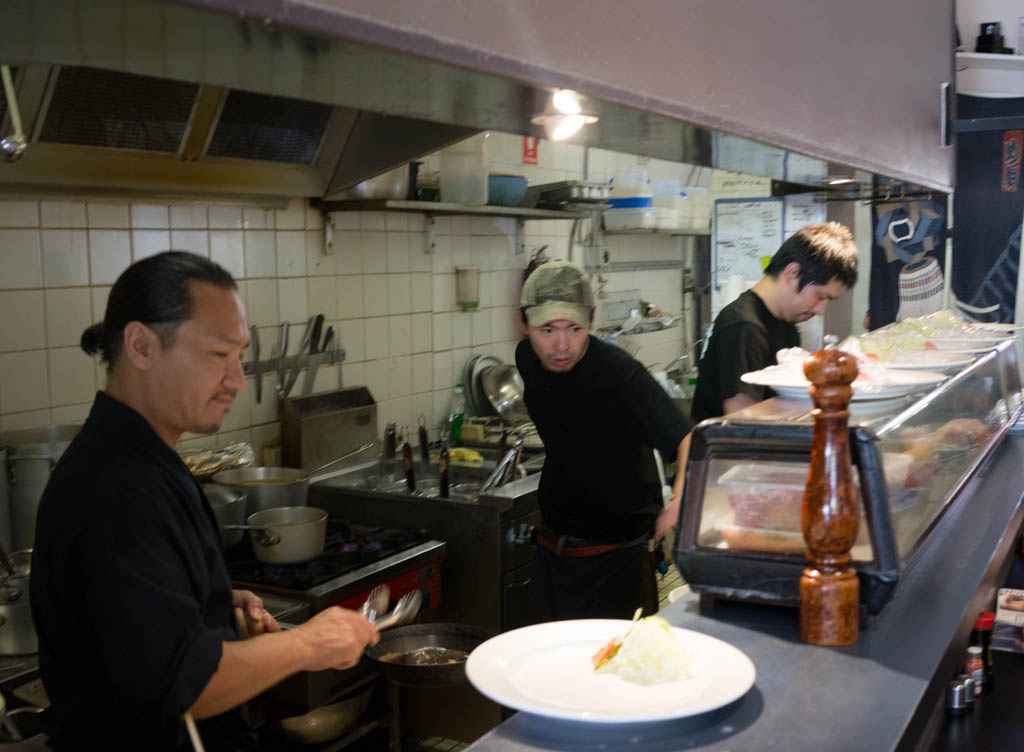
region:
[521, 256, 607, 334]
hat on man's head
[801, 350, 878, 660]
wooden pole on counter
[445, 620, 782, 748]
white plate on counter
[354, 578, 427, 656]
tongs in man's hand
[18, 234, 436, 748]
cook at the restaurant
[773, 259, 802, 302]
right ear on guy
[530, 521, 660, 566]
belt on man's waist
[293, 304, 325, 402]
knife hanging on rack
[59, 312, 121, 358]
ponytail in man's head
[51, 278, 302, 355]
Man has dark hair.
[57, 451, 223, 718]
Man wearing black shirt.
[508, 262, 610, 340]
Man wearing baseball cap.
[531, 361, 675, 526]
Man wearing black shirt.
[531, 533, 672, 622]
Man wearing black pants.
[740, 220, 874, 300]
Man has short hair.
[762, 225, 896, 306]
Man has black hair.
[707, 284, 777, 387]
Man wearing black shirt.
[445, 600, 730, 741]
White bowl on counter top.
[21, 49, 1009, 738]
picture of a kitchen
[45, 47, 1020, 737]
kitchen is in a restaurant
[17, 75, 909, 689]
three male chefs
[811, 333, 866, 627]
a tall pepper mill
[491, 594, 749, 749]
a white bowl on top of the counter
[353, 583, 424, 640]
the man holds metal tongs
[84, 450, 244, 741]
the man wears a black shirt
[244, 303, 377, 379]
knives are on the wall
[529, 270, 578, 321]
the man wears a green hat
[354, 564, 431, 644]
Man holding tongs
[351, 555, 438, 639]
Man is holding tongs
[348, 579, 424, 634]
Man holding a pair of tongs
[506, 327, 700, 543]
Man wearing a shirt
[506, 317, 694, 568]
Man is wearing a shirt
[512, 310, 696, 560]
Man wearing a black shirt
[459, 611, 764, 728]
White plate on a counter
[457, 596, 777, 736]
White plate is on a counter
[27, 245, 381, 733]
chef wearing a black colored shirt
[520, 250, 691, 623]
chef wearing a black colored shirt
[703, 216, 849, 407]
chef wearing a black colored shirt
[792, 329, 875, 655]
big wooden pole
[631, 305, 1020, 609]
display of food preparation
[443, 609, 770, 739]
plate on the lower counter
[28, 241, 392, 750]
man with a ponytail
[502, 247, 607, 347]
green colored baseball cap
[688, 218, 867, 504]
man looking down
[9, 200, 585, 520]
white tiled wall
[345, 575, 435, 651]
tongs in a man's hand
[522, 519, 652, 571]
brown belt on a man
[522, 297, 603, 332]
bill of a baseball cap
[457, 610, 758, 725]
large white plate on the counter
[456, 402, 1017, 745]
gray silver counter top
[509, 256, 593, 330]
tan colored baseball cap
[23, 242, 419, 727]
man holding silver tongs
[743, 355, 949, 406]
large white plate on the counter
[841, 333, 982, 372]
large white plate on the counte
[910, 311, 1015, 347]
large white plate on the counte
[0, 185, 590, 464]
beige tile covering the wall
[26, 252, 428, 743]
man wearing black hair in pony tail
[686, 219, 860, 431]
man wearing black tee shirt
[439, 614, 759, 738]
White plate on a counter.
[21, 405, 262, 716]
Black shirt on a man.